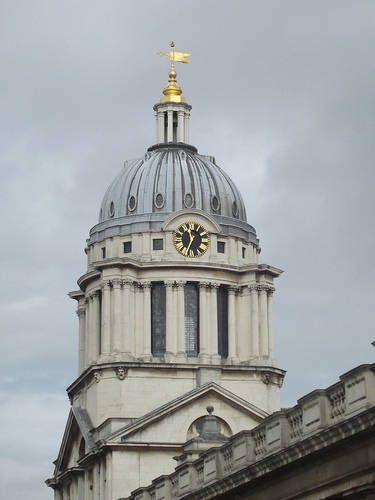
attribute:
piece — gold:
[155, 38, 193, 104]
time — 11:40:
[183, 221, 196, 255]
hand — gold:
[184, 235, 195, 254]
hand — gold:
[185, 227, 194, 240]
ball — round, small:
[192, 401, 223, 414]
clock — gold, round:
[171, 220, 211, 260]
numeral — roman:
[187, 221, 198, 233]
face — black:
[174, 224, 208, 256]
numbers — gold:
[176, 236, 188, 253]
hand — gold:
[183, 228, 197, 251]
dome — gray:
[89, 138, 250, 225]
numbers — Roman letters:
[172, 220, 212, 259]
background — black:
[176, 224, 209, 256]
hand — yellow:
[187, 227, 194, 240]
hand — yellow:
[184, 233, 194, 255]